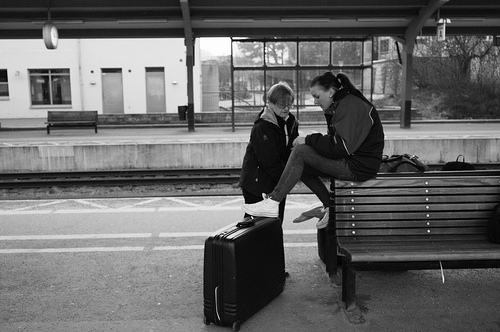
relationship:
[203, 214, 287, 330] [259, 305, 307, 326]
suitcase sitting on ground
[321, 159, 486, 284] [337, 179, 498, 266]
bolt in bench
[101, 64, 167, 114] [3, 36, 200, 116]
doors on building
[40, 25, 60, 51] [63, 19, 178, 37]
clock hanging from roof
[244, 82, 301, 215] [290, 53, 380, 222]
woman and a woman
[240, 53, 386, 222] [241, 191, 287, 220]
woman wearing tennis shoe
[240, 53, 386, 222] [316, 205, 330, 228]
woman wearing sneaker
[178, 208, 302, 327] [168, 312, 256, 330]
suitcase with wheels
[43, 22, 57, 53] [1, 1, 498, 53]
clock hanging from ceiling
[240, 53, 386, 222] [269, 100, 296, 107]
woman wearing glasses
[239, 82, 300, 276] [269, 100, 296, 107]
woman wearing glasses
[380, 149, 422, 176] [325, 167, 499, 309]
bag sitting on bench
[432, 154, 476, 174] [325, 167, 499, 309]
bag sitting on bench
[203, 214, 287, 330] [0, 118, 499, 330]
suitcase sitting on pavement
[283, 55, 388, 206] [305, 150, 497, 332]
girl sitting on bench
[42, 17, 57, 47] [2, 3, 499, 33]
clock hanging from roof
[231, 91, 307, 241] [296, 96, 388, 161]
person wearing jacket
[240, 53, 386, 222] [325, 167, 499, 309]
woman sitting on bench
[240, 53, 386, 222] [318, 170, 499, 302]
woman sitting on bench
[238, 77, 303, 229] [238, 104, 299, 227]
person wearing dark jacket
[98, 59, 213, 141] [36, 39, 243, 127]
door leading to building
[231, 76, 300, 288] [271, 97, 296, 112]
person wearing glasses